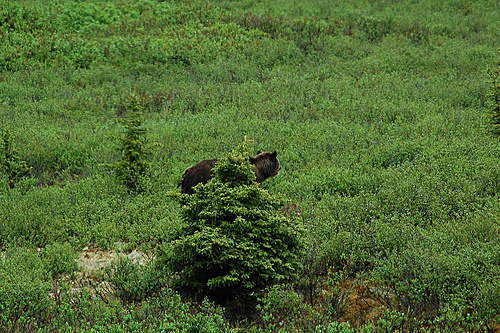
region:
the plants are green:
[357, 197, 475, 283]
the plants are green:
[353, 177, 443, 267]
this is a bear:
[185, 133, 298, 184]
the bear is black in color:
[186, 138, 285, 186]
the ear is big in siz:
[268, 146, 283, 159]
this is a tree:
[176, 186, 293, 284]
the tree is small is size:
[176, 186, 304, 282]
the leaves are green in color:
[316, 92, 498, 270]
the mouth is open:
[274, 163, 286, 172]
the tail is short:
[178, 171, 191, 185]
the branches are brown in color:
[321, 281, 376, 313]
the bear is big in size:
[181, 147, 283, 192]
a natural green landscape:
[36, 15, 494, 310]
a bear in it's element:
[106, 71, 417, 291]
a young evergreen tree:
[99, 77, 173, 197]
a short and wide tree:
[164, 126, 322, 306]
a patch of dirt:
[20, 204, 185, 319]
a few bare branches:
[293, 221, 473, 332]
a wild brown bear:
[164, 129, 302, 214]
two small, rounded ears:
[250, 138, 287, 163]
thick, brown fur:
[191, 165, 212, 182]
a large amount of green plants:
[199, 36, 455, 112]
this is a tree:
[168, 134, 307, 325]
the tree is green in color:
[171, 140, 293, 317]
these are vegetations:
[321, 121, 437, 253]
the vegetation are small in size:
[316, 81, 439, 287]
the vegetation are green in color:
[325, 5, 440, 247]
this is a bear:
[177, 141, 298, 204]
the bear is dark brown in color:
[158, 140, 285, 203]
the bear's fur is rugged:
[183, 156, 284, 191]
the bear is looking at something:
[228, 135, 300, 191]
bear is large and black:
[171, 141, 290, 198]